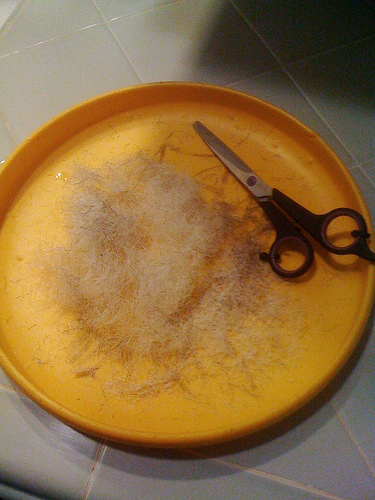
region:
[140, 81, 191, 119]
this is a plate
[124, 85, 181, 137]
the plate is yellow in color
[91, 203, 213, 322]
these are hairs on the plate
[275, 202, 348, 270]
this is a scissor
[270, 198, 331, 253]
the handles are black in color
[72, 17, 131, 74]
the floor is tiled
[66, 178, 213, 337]
the hairs are white in color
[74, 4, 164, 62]
the floor is white in color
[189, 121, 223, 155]
the tip is sharp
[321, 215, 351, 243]
the handle has hole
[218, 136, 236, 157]
edge of a scissor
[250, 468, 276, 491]
part of a line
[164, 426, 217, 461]
edge of a dish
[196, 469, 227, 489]
edge of a shade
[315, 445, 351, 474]
part of a surface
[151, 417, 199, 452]
edge of a tray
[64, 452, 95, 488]
edge of a shade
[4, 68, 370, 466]
orange plate with short rim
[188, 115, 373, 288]
scissors with black handles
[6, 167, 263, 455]
cur white and grey hairs on plate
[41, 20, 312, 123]
plate on light gray tiles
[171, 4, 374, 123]
angled shadow on top of plate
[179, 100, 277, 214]
closed metallic blades of scissors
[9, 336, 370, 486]
shadow of arc of plate on tile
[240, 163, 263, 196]
dark metal screw connecting scissor parts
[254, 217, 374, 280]
black notch and circles on scissor openings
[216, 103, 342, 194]
shiny curve on inside of plate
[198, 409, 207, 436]
the plate is yellow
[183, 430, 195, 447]
the plate is yellow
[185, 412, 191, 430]
the plate is yellow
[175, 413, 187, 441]
the plate is yellow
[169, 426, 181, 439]
the plate is yellow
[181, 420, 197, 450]
the plate is yellow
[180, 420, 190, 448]
the plate is yellow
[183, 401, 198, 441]
the plate is yellow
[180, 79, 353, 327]
a scissors